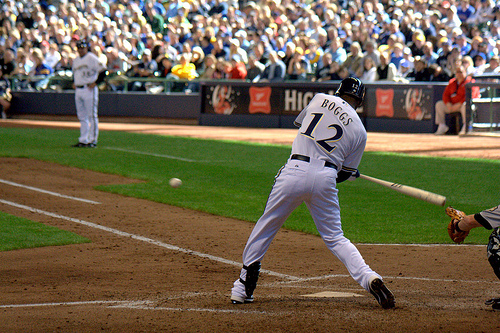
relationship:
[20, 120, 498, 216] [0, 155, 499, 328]
grass on baseball field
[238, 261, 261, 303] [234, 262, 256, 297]
padding on ankle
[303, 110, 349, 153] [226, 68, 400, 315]
number on batter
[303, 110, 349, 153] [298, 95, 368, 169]
number on jersey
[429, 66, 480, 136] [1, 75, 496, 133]
man by fence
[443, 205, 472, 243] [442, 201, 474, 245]
hand wearing glove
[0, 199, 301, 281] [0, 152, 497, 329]
line painted on ground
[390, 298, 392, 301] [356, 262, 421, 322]
stud attached to shoe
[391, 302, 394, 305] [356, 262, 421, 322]
stud attached to shoe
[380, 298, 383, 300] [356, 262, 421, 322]
stud attached to shoe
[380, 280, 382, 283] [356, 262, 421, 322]
stud attached to shoe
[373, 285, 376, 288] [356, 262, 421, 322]
stud attached to shoe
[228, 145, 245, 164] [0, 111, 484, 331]
grass growing on ground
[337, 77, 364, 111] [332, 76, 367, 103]
head wearing on helmet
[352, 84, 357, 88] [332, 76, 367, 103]
number displayed on helmet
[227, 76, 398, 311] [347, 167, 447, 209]
batter swinging bat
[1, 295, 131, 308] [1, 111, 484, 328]
line painted on baseball field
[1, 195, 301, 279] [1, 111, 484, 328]
line painted on baseball field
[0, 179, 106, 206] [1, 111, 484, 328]
line painted on baseball field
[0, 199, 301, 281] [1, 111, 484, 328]
line painted on baseball field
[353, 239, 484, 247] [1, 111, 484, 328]
line painted on baseball field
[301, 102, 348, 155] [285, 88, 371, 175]
number sewn on jersey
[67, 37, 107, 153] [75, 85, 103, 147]
man wearing pants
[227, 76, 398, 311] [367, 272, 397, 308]
batter wearing shoe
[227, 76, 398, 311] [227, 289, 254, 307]
batter wearing shoe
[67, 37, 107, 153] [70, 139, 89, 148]
man wearing shoe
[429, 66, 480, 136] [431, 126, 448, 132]
man wearing shoe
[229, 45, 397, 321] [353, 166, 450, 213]
batter holding bat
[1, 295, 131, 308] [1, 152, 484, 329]
line painted on dirt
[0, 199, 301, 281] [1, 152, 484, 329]
line painted on dirt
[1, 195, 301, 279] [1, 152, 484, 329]
line painted on dirt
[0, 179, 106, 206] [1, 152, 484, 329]
line painted on dirt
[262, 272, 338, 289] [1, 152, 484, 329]
line painted on dirt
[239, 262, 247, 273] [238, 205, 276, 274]
strap carried around leg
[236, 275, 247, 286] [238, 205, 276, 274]
strap carried around leg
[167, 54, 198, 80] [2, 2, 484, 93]
spectator sitting in stands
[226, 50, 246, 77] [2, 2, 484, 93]
spectator sitting in stands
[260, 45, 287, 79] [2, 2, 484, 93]
spectator sitting in stands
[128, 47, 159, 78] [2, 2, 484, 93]
spectator sitting in stands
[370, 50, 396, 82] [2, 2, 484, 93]
spectator sitting in stands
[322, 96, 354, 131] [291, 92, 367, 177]
name sewn on jersey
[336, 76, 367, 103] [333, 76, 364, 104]
helmet on head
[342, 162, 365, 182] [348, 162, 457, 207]
hand on bat